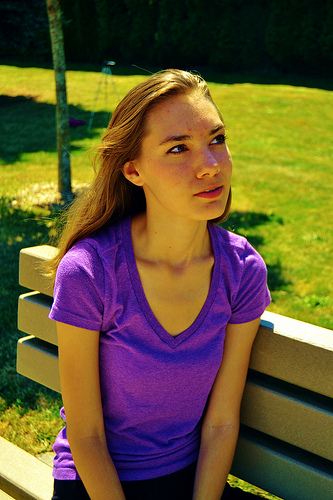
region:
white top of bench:
[285, 309, 322, 355]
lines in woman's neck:
[180, 238, 211, 274]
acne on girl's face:
[181, 114, 210, 132]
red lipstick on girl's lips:
[182, 180, 229, 203]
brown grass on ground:
[9, 407, 33, 432]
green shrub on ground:
[287, 217, 328, 254]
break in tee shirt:
[112, 329, 218, 371]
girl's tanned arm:
[35, 333, 130, 463]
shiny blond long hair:
[72, 49, 160, 245]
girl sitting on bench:
[64, 60, 285, 427]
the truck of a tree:
[39, 1, 82, 203]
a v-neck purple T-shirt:
[76, 213, 262, 491]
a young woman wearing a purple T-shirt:
[60, 59, 261, 480]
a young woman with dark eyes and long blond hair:
[53, 41, 275, 241]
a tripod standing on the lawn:
[86, 55, 121, 125]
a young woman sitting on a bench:
[2, 54, 332, 496]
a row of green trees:
[2, 0, 332, 82]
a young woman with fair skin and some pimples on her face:
[79, 58, 272, 253]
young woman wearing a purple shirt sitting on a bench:
[43, 40, 302, 498]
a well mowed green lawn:
[235, 79, 332, 236]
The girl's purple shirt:
[43, 205, 274, 485]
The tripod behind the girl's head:
[73, 64, 131, 136]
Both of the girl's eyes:
[159, 131, 230, 155]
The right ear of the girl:
[120, 157, 145, 188]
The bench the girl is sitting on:
[2, 239, 332, 497]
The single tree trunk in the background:
[40, 0, 77, 212]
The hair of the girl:
[33, 65, 210, 284]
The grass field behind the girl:
[0, 64, 332, 455]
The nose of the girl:
[194, 144, 219, 180]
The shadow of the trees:
[0, 91, 291, 413]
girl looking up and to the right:
[111, 70, 254, 256]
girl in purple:
[59, 226, 282, 459]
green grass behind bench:
[254, 99, 323, 197]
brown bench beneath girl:
[4, 233, 63, 388]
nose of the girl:
[193, 144, 222, 182]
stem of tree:
[31, 33, 81, 179]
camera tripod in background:
[88, 48, 135, 88]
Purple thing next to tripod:
[70, 107, 91, 142]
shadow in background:
[0, 82, 82, 162]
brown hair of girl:
[49, 70, 170, 218]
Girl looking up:
[87, 79, 268, 307]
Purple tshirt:
[87, 220, 255, 456]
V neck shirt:
[96, 214, 245, 338]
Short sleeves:
[36, 294, 331, 345]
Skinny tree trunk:
[20, 47, 87, 199]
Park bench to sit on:
[13, 222, 327, 438]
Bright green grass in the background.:
[10, 44, 317, 199]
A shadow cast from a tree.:
[6, 86, 93, 147]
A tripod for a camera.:
[76, 51, 121, 117]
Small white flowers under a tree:
[14, 182, 92, 200]